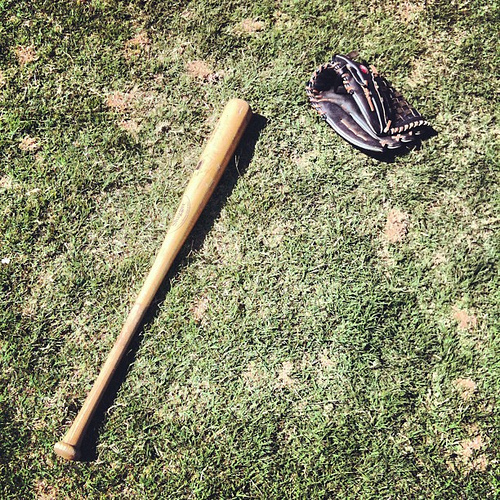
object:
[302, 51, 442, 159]
baseball glove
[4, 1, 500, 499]
ground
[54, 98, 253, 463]
baseball bat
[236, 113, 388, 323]
grass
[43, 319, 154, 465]
handle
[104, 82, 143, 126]
brown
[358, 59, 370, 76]
label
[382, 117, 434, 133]
stitching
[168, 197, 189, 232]
label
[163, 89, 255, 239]
barrel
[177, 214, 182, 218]
black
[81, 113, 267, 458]
shadow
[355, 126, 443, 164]
shadow